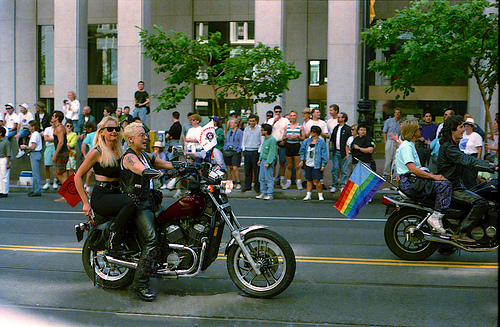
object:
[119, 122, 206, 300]
person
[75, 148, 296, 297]
motorcycle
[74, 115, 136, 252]
person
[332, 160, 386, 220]
flag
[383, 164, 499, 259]
motorcycle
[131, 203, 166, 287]
chaps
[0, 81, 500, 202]
spectators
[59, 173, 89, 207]
flag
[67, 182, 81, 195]
circle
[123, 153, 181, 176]
arm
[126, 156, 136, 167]
tattoo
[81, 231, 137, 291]
tire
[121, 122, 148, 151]
head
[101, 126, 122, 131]
sunglasses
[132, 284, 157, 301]
boot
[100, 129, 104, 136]
ear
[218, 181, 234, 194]
headlight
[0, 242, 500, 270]
line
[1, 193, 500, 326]
road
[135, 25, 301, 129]
tree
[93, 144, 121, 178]
crop top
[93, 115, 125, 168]
hair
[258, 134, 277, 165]
shirt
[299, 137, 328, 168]
jacket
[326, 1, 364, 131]
pillar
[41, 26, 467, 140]
reflection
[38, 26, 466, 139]
glass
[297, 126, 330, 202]
person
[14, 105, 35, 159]
person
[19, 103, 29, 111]
hat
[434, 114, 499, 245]
man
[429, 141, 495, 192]
jacket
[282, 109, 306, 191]
person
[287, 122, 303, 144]
shirt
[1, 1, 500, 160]
building